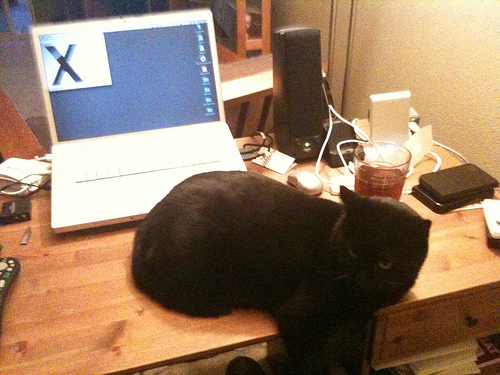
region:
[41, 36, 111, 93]
white patch on screen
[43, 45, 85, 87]
letter x on screen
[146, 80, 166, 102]
black screen on computer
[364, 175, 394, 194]
juice in glass cup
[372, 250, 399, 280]
right eye on cat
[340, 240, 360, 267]
left eye on cat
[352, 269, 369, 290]
cat has black nose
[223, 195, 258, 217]
black hair on cats back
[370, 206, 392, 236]
black hair on cats head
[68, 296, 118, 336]
top of brown counter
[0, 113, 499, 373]
Light colored wooden desk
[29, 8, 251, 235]
White laptop computer on desk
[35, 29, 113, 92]
X on laptop screen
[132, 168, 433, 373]
Black cat on desk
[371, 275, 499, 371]
Drawer built into desk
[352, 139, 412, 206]
Glass with brown liquid in it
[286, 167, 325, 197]
White computer mouse on desk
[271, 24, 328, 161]
Small black computer speaker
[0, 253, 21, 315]
Black remote control on desk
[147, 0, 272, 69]
Light colored wooden bookcase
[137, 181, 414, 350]
A cat on the desk.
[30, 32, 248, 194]
A laptop on the desk.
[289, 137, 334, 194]
Mouse on the desk.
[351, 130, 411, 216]
A glass next to the cat.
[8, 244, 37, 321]
Remote control on the desk.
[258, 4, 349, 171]
Speakers on the desk.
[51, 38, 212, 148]
The screen is on.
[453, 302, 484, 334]
The knob on the drawer.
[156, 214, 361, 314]
The cat is black.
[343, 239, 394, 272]
Eyes on the cat.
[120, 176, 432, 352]
Black cat on the desk.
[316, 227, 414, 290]
Black cat with green eyes.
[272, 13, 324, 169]
Black speaker on the desk.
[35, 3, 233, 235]
White laptop on the desk.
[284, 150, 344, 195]
White mouse on the desk.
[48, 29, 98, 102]
Blue X on the screen.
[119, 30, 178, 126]
Blue background on the screen.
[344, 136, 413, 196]
Glass of tea on the desk.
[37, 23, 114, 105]
Blue X on a white background.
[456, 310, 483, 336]
Black knob on the desk drawer.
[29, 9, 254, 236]
White laptop on desk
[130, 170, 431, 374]
Black cat laying on desk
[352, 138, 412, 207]
Glass with brown liquid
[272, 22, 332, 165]
Black speaker on desk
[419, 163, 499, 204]
Black cell phone on desk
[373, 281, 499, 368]
Wooden drawer attached to desk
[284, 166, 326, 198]
White mouse behind cat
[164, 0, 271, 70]
Wooden book shelf against wall